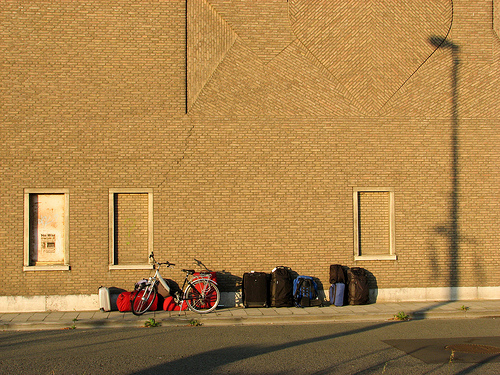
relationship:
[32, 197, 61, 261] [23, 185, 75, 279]
plywood covers window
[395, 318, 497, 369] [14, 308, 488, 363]
manhole covers road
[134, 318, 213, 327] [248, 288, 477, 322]
vegetation near sidewalk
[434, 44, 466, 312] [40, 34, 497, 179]
shadow cast on wall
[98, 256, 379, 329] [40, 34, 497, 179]
luggage near wall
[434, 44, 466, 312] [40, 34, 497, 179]
shadow on wall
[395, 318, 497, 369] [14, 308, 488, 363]
manhole lying on road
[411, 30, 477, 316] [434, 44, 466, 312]
pole has shadow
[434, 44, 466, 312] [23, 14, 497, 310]
shadow on building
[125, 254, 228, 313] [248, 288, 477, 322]
bike parked on sidewalk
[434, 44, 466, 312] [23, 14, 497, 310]
shadow shown on building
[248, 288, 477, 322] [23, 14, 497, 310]
sidewalk near building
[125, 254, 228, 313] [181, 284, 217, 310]
bike has tire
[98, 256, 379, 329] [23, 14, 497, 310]
luggage near building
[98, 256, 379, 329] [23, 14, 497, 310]
bags near building